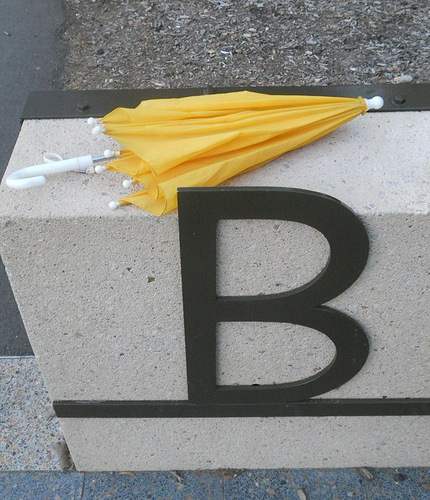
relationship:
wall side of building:
[15, 123, 413, 474] [41, 107, 414, 492]